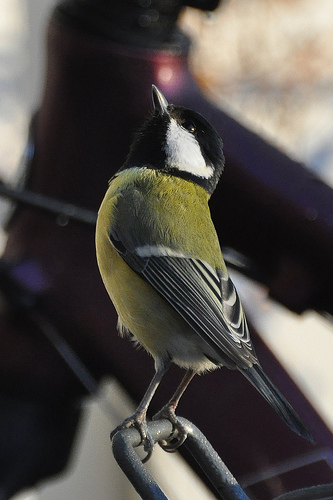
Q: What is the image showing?
A: A bird.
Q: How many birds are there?
A: One.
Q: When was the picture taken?
A: Daytime.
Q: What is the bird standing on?
A: A metal perch.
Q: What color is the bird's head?
A: Black and white.